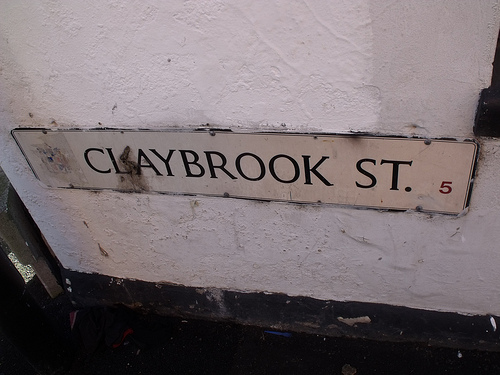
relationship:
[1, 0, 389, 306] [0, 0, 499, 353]
stucco on wall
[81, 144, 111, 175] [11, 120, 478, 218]
letter on sign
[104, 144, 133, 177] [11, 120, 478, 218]
letter on sign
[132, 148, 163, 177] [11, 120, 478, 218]
letter on sign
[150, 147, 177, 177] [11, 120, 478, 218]
letter on sign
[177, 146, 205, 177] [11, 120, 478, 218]
letter on sign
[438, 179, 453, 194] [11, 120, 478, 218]
number on sign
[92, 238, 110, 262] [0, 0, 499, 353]
dirt speck on wall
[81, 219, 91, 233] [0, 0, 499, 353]
dirt speck on wall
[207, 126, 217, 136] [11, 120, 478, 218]
screw on sign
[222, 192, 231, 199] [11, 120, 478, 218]
screw on sign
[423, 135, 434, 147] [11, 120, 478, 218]
screw on sign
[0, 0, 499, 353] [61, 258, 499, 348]
wall has strip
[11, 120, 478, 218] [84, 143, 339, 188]
sign has word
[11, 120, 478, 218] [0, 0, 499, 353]
sign on wall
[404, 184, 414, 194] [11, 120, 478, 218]
point on sign